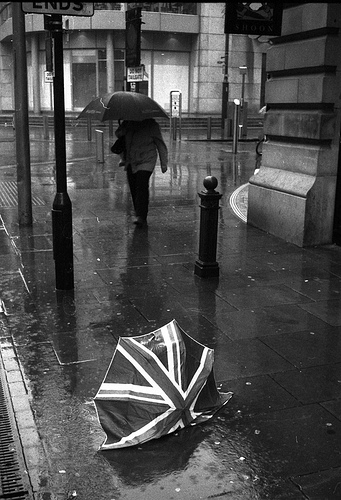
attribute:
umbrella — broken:
[71, 309, 226, 449]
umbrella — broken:
[92, 325, 237, 455]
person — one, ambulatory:
[81, 85, 177, 225]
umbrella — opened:
[84, 324, 236, 446]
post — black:
[189, 169, 228, 284]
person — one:
[116, 123, 169, 225]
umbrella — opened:
[76, 89, 174, 122]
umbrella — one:
[87, 93, 175, 122]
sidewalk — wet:
[0, 125, 338, 497]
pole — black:
[47, 14, 76, 291]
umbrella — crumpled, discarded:
[92, 316, 233, 452]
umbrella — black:
[76, 91, 168, 126]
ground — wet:
[0, 127, 340, 499]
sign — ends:
[19, 1, 93, 18]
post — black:
[45, 16, 75, 291]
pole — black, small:
[192, 174, 224, 278]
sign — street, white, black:
[126, 64, 145, 83]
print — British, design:
[93, 318, 234, 451]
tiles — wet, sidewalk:
[93, 259, 190, 312]